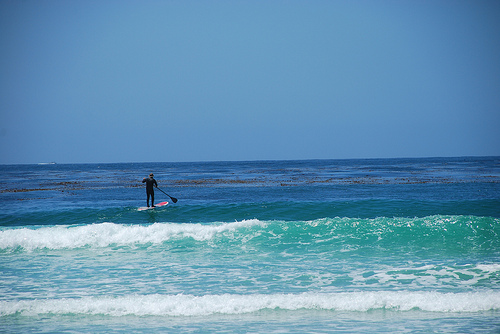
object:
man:
[141, 173, 157, 208]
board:
[135, 198, 169, 213]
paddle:
[152, 184, 180, 204]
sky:
[1, 1, 500, 163]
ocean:
[0, 155, 498, 333]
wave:
[2, 207, 499, 315]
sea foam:
[3, 216, 267, 259]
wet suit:
[141, 176, 160, 210]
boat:
[37, 160, 57, 168]